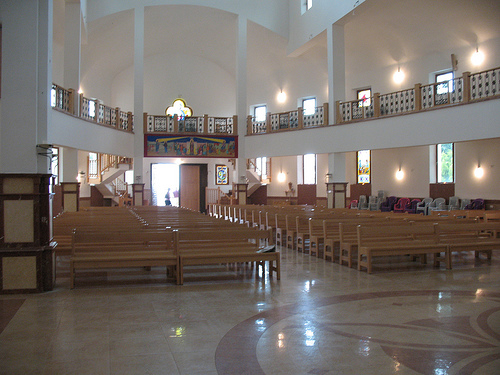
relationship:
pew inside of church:
[72, 235, 284, 273] [5, 8, 495, 372]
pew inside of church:
[50, 204, 499, 289] [5, 8, 495, 372]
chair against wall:
[381, 195, 396, 209] [370, 153, 425, 197]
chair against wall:
[381, 196, 485, 218] [452, 145, 499, 199]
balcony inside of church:
[249, 125, 369, 155] [5, 8, 495, 372]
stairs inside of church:
[90, 160, 128, 180] [5, 8, 495, 372]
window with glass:
[354, 151, 376, 185] [363, 164, 369, 178]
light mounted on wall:
[395, 171, 405, 180] [370, 153, 425, 197]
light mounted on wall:
[473, 166, 487, 180] [452, 145, 499, 199]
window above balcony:
[166, 98, 192, 118] [249, 125, 369, 155]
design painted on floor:
[222, 288, 499, 374] [16, 286, 499, 371]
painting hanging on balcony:
[144, 135, 242, 162] [40, 131, 250, 149]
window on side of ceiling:
[296, 1, 320, 16] [67, 3, 474, 69]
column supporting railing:
[416, 86, 422, 112] [381, 93, 417, 115]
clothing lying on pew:
[259, 246, 281, 256] [72, 235, 284, 273]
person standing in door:
[164, 187, 170, 204] [152, 166, 181, 207]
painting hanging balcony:
[144, 135, 242, 162] [249, 125, 369, 155]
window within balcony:
[252, 104, 274, 125] [249, 125, 369, 155]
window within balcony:
[299, 96, 322, 115] [249, 125, 369, 155]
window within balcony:
[432, 76, 457, 100] [249, 125, 369, 155]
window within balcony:
[356, 90, 378, 110] [249, 125, 369, 155]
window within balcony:
[88, 93, 109, 120] [249, 125, 369, 155]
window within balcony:
[51, 77, 66, 106] [249, 125, 369, 155]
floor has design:
[16, 286, 499, 371] [222, 288, 499, 374]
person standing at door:
[164, 187, 170, 204] [152, 166, 181, 207]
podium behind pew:
[250, 184, 269, 204] [207, 205, 211, 213]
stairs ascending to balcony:
[90, 160, 128, 180] [249, 125, 369, 155]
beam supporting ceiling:
[328, 28, 345, 126] [67, 3, 474, 69]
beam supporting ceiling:
[233, 26, 247, 135] [67, 3, 474, 69]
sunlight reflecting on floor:
[303, 326, 322, 352] [16, 286, 499, 371]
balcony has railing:
[249, 125, 369, 155] [273, 112, 319, 127]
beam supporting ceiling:
[129, 8, 149, 131] [67, 3, 474, 69]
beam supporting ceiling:
[64, 10, 86, 95] [67, 3, 474, 69]